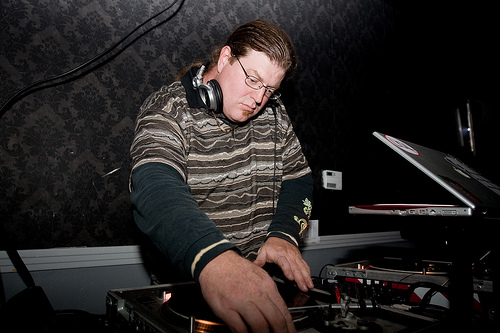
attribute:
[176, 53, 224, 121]
headphone — black, silver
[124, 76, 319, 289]
shirt — brown, striped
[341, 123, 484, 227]
laptop — open, silver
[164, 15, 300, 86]
hair — brown, medium length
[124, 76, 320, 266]
shirt — striped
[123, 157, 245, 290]
sleeve — long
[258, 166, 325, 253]
sleeve — long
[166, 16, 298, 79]
hair — brown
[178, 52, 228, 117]
headset — black, silver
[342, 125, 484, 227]
macbook — silver, opened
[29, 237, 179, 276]
trim — white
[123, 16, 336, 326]
man — standing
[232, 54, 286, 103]
glasses — reading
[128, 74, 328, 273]
shirt — long sleeve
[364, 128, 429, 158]
sticker — white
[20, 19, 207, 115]
wire — black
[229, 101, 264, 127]
chin — hairy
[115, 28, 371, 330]
man — performing, DJ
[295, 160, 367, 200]
box — white